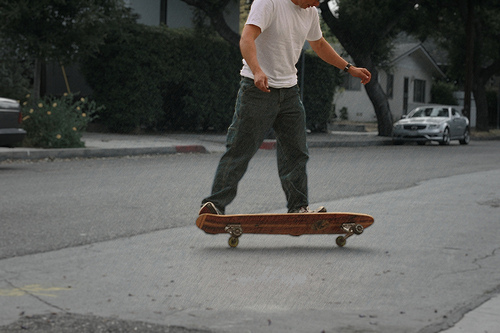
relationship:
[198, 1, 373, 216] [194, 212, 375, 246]
man on skateboard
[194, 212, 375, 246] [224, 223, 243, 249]
skateboard has wheels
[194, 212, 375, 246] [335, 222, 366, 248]
skateboard has wheels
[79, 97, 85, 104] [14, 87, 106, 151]
flower on plant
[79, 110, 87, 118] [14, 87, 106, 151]
flower on plant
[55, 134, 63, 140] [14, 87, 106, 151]
flower on plant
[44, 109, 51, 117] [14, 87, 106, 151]
flower on plant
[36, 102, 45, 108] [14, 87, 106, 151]
flower on plant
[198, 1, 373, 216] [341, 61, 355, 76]
man wearing watch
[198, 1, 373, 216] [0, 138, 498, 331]
man on street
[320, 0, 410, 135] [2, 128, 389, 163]
tree on sidewalk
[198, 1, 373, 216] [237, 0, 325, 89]
man wearing a shirt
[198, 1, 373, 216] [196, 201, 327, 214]
man wearing shoes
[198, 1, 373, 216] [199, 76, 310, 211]
man wearing jeans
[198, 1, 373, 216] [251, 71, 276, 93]
man has a hand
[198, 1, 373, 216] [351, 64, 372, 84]
man has a hand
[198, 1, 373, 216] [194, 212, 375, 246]
man on a skateboard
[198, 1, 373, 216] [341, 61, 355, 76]
man wearing a watch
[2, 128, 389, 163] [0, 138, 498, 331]
sidewalk beside of street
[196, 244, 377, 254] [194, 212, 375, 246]
shadow of a skateboard